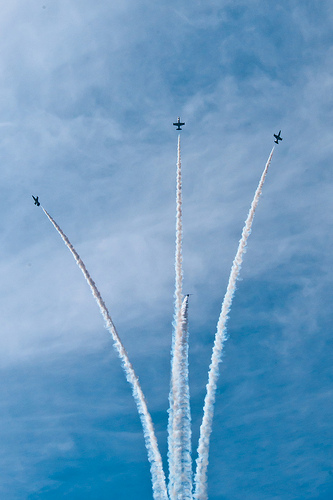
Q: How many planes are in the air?
A: Four.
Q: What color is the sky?
A: Blue.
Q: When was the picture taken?
A: During the day.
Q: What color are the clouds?
A: White.